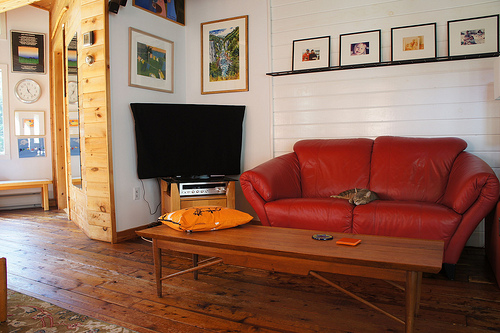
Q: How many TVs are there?
A: One.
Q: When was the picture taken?
A: Daytime.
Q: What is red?
A: Couch.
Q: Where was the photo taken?
A: In a living room.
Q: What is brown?
A: Floor.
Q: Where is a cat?
A: On the couch.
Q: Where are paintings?
A: On the wall.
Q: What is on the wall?
A: Clock.